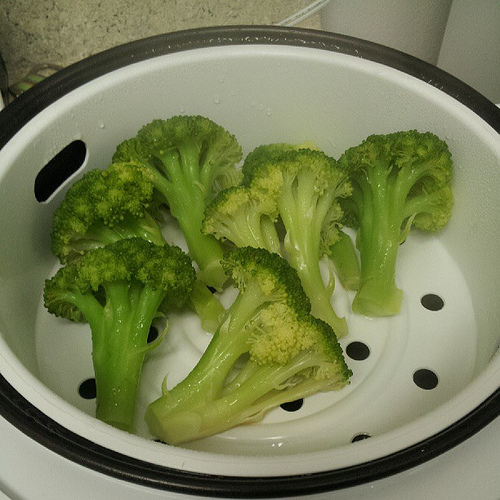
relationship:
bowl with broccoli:
[6, 42, 498, 482] [144, 241, 364, 448]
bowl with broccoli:
[6, 42, 498, 482] [199, 142, 353, 338]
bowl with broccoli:
[6, 42, 498, 482] [112, 113, 241, 290]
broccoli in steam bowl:
[332, 114, 458, 324] [0, 26, 498, 496]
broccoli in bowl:
[38, 115, 455, 445] [6, 42, 498, 482]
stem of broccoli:
[348, 208, 409, 320] [341, 123, 461, 324]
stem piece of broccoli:
[90, 293, 147, 427] [144, 241, 364, 448]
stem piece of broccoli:
[348, 184, 406, 313] [144, 241, 364, 448]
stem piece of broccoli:
[172, 192, 230, 288] [112, 113, 241, 290]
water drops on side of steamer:
[63, 101, 115, 134] [0, 25, 497, 498]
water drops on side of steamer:
[206, 86, 283, 119] [0, 25, 497, 498]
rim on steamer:
[163, 22, 401, 61] [25, 25, 499, 455]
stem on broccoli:
[348, 208, 409, 320] [332, 114, 458, 324]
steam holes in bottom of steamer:
[341, 287, 448, 364] [137, 45, 437, 138]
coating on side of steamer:
[0, 43, 498, 374] [0, 25, 497, 498]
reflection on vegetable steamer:
[7, 0, 498, 150] [0, 25, 500, 495]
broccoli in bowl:
[332, 114, 458, 324] [6, 42, 498, 482]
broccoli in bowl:
[144, 241, 364, 448] [6, 42, 498, 482]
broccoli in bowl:
[103, 100, 250, 286] [6, 42, 498, 482]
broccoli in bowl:
[144, 241, 364, 448] [370, 306, 499, 416]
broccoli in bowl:
[103, 100, 250, 286] [370, 306, 499, 416]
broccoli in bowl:
[103, 100, 250, 286] [88, 62, 467, 459]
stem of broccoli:
[85, 287, 155, 425] [144, 241, 364, 448]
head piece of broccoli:
[38, 237, 198, 319] [144, 241, 364, 448]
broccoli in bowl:
[144, 241, 364, 448] [2, 22, 478, 471]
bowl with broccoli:
[6, 42, 498, 482] [38, 115, 455, 445]